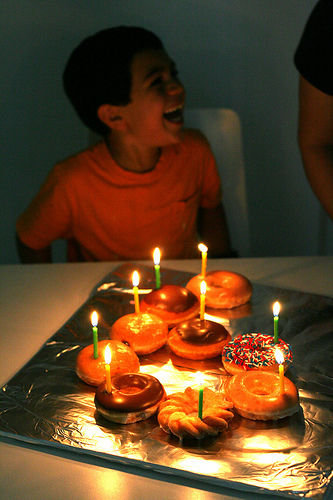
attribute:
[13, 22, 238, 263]
child — smiling, little, laughing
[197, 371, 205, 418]
candle — lit, birthday candle, green, small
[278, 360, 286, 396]
candle — yellow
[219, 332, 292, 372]
sprinkles — rainbow, red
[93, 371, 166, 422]
doughnut — glazed, chocolate, frosted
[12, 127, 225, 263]
t-shirt — orange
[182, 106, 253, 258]
chair — white, blue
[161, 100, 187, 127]
mouth — open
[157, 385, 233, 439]
cruller — glazed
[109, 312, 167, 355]
doughnut — jelly filled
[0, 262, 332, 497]
pan — square